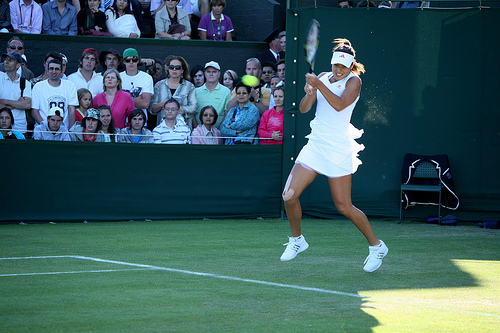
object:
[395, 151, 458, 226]
blue chair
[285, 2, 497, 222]
wall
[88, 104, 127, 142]
woman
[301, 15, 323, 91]
racket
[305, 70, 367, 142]
tennis top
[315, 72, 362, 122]
t shirt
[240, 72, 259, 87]
ball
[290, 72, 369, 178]
dress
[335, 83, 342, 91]
symbol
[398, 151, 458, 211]
jacket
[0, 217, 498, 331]
ground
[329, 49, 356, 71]
visor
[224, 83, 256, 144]
woman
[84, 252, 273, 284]
line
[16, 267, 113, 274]
line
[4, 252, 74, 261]
line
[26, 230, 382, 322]
court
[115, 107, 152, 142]
man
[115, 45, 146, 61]
cap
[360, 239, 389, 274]
shoe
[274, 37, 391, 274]
woman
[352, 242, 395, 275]
tennis shoes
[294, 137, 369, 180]
skirt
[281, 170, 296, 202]
bandage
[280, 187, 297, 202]
knee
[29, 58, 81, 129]
man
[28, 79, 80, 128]
shirt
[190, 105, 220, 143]
woman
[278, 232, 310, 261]
shoe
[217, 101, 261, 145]
shirt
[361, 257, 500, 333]
sunlight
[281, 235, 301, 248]
shoestrings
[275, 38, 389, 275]
player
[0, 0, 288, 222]
stands